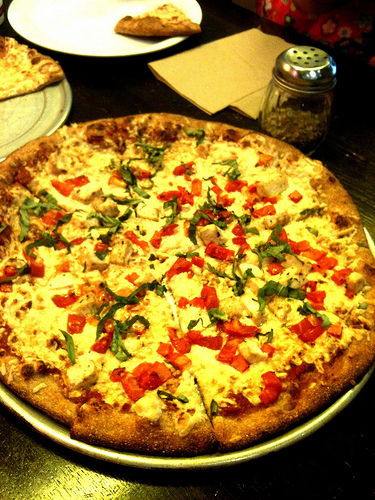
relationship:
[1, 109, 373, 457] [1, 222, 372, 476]
pizza on tray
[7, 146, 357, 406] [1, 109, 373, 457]
toppings on pizza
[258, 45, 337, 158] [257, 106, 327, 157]
shaker has oregano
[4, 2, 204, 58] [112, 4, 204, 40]
plate has slice of pizza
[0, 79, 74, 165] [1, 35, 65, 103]
pan has slice of pizza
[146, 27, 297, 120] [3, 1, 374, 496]
napkin on table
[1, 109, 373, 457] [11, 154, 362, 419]
pizza has chicken topping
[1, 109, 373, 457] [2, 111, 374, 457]
pizza has crust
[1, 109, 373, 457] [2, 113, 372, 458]
pizza has slices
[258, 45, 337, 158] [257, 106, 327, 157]
jar of seasoning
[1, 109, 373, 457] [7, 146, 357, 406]
pizza has toppings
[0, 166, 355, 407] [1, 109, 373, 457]
tomatoes on pizza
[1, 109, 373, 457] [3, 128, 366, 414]
pizza has green toppings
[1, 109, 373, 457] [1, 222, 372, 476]
pizza on pan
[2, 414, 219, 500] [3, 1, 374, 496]
light reflecting on table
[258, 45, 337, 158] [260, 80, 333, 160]
shaker made of glass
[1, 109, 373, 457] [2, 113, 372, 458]
pizza cut into triangles